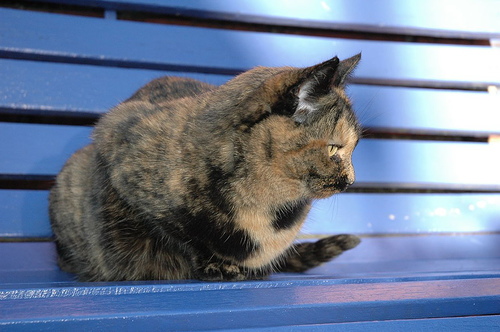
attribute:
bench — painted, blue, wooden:
[4, 2, 496, 326]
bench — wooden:
[487, 20, 497, 54]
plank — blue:
[2, 8, 498, 79]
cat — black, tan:
[59, 70, 401, 281]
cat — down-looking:
[49, 43, 386, 302]